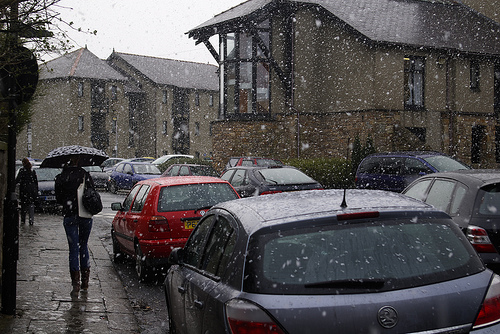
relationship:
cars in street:
[23, 153, 499, 323] [9, 142, 498, 332]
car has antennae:
[115, 180, 229, 258] [334, 144, 355, 208]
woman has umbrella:
[53, 165, 103, 295] [40, 144, 108, 169]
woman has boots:
[53, 165, 103, 295] [68, 267, 91, 296]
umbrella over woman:
[40, 144, 108, 169] [53, 165, 103, 295]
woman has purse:
[53, 165, 103, 295] [78, 175, 101, 215]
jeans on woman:
[62, 210, 101, 284] [53, 165, 103, 295]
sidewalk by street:
[12, 194, 130, 329] [9, 142, 498, 332]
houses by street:
[29, 0, 497, 176] [9, 142, 498, 332]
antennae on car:
[334, 144, 355, 208] [115, 180, 229, 258]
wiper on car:
[308, 276, 387, 295] [115, 180, 229, 258]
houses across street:
[29, 0, 497, 176] [9, 142, 498, 332]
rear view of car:
[239, 204, 483, 322] [115, 180, 229, 258]